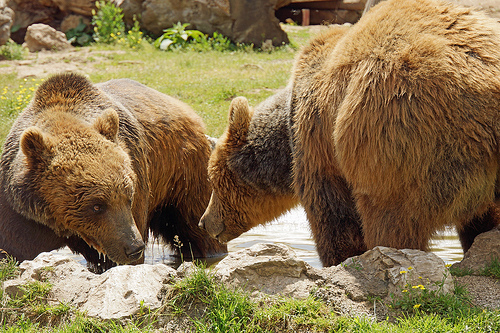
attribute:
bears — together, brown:
[23, 38, 416, 226]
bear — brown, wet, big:
[6, 56, 170, 249]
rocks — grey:
[58, 251, 400, 286]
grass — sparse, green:
[190, 281, 279, 332]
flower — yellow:
[102, 26, 141, 44]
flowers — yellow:
[87, 1, 155, 46]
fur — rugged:
[74, 92, 124, 115]